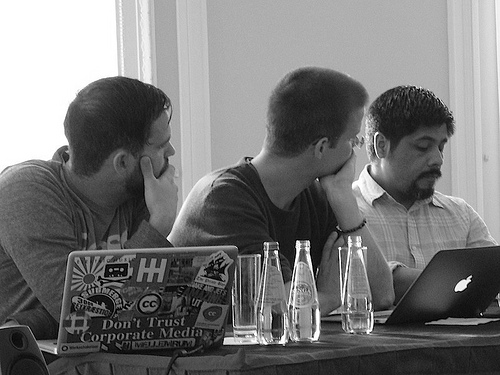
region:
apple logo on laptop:
[454, 274, 475, 297]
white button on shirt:
[409, 240, 421, 253]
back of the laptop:
[390, 249, 498, 322]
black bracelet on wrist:
[334, 217, 376, 236]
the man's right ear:
[315, 133, 326, 170]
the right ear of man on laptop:
[373, 128, 387, 164]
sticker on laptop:
[192, 251, 233, 291]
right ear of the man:
[112, 152, 133, 177]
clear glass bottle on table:
[292, 239, 323, 346]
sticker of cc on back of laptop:
[138, 291, 159, 312]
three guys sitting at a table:
[2, 40, 499, 371]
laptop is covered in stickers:
[46, 245, 244, 359]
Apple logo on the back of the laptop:
[453, 271, 476, 294]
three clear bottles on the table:
[240, 233, 394, 343]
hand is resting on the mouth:
[137, 153, 193, 233]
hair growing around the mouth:
[401, 161, 446, 204]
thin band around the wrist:
[330, 215, 371, 240]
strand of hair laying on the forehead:
[164, 105, 176, 125]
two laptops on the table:
[23, 220, 499, 357]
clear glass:
[225, 255, 260, 333]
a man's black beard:
[401, 165, 448, 202]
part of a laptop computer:
[326, 242, 498, 324]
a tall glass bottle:
[340, 235, 379, 337]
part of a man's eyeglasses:
[323, 128, 370, 153]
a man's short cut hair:
[62, 72, 177, 183]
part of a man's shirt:
[352, 162, 496, 274]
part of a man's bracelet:
[330, 219, 369, 236]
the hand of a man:
[135, 160, 182, 232]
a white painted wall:
[210, 2, 442, 64]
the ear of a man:
[110, 150, 131, 175]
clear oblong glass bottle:
[340, 232, 376, 338]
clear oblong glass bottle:
[287, 233, 324, 345]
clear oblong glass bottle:
[250, 242, 292, 349]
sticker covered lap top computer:
[54, 242, 239, 359]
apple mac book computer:
[385, 246, 499, 336]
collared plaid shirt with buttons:
[337, 161, 497, 277]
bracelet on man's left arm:
[333, 214, 372, 239]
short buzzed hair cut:
[259, 60, 372, 162]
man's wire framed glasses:
[308, 129, 365, 151]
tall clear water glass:
[225, 248, 264, 348]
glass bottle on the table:
[336, 227, 376, 337]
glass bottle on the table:
[284, 232, 332, 345]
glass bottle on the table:
[252, 238, 292, 345]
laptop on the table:
[30, 236, 250, 360]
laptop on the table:
[347, 233, 499, 328]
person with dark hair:
[328, 78, 495, 311]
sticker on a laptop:
[126, 250, 174, 288]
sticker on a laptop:
[100, 260, 132, 282]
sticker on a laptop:
[132, 290, 162, 320]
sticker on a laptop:
[190, 295, 232, 336]